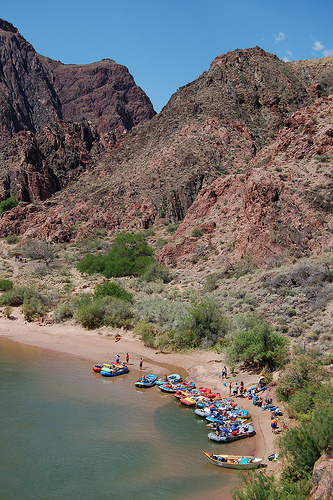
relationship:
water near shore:
[0, 335, 257, 499] [4, 307, 296, 498]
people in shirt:
[126, 352, 130, 363] [122, 355, 131, 361]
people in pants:
[126, 352, 130, 363] [134, 361, 145, 367]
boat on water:
[134, 373, 158, 389] [77, 402, 198, 468]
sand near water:
[60, 327, 154, 368] [11, 380, 135, 494]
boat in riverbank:
[202, 445, 263, 468] [103, 336, 259, 458]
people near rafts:
[115, 355, 121, 363] [158, 365, 257, 445]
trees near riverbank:
[63, 229, 199, 337] [44, 244, 327, 444]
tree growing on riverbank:
[154, 333, 169, 354] [2, 324, 299, 498]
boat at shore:
[91, 362, 120, 372] [64, 315, 265, 391]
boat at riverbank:
[202, 445, 263, 468] [0, 305, 299, 500]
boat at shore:
[202, 445, 263, 468] [4, 307, 296, 498]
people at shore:
[108, 326, 282, 436] [4, 307, 296, 498]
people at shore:
[123, 351, 130, 364] [0, 326, 283, 499]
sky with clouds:
[149, 26, 323, 58] [271, 29, 330, 56]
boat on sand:
[202, 445, 263, 468] [258, 425, 283, 482]